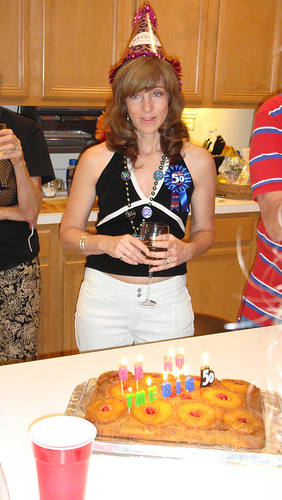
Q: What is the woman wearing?
A: A hat.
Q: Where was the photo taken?
A: In the kitchen.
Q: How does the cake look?
A: Delicious.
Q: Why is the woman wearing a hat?
A: It's her birthday.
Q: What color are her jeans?
A: White.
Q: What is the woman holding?
A: A wine glass.